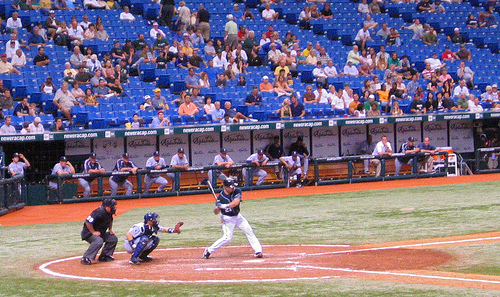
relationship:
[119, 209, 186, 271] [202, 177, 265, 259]
baseball player holding glove player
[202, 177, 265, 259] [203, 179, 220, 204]
player with bat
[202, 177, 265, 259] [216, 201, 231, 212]
player has hand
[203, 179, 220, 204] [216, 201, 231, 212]
bat in hand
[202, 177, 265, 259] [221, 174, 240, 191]
player has baseball helmet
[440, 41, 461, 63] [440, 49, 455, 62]
man wearing shirt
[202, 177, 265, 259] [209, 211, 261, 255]
player wearing pants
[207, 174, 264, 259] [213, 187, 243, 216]
player wearing shirt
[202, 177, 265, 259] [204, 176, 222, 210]
player holding bat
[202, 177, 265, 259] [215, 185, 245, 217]
player wearing shirt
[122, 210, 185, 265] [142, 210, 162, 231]
baseball player wearing helmet